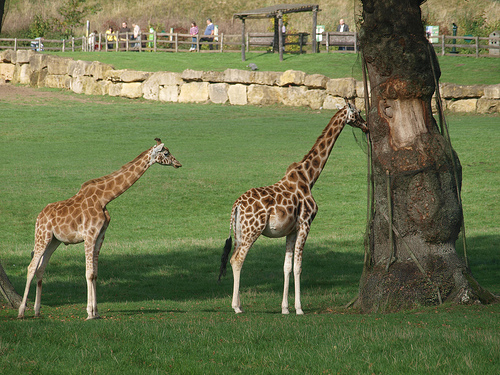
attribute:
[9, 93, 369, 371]
field — large, green, grassy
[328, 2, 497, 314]
tree trunk — dark brown, gray, thick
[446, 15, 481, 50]
telescope — green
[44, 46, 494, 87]
grass — green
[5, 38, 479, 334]
enclosure — giraffe